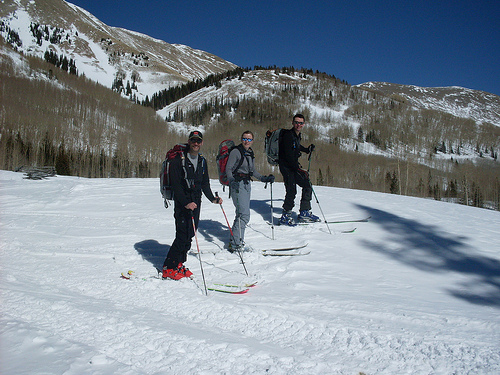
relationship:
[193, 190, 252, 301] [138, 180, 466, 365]
pole used skiing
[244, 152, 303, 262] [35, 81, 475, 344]
pole used skiing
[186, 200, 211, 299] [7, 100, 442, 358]
pole used skiing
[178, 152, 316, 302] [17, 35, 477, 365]
pole used skiing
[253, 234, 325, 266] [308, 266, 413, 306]
ski covered snow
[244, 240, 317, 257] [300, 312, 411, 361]
ski covered snow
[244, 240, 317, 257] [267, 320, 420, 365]
ski covered snow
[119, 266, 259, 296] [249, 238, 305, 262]
ski covered snow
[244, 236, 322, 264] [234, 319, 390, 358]
ski covered snow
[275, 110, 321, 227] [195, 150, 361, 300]
man on skies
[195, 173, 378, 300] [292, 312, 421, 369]
skies in snow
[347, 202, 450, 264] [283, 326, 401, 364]
shadow on snow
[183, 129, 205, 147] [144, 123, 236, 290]
hat on man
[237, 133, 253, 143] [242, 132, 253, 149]
glasses on face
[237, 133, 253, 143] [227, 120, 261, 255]
glasses on man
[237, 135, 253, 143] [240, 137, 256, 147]
glasses of glasses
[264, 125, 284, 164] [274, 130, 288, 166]
pack of back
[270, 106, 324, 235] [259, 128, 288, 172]
man wearing backpack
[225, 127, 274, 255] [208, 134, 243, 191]
man wearing backpack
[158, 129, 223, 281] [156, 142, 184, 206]
man wearing backpack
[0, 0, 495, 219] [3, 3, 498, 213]
range in back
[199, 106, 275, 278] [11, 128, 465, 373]
man on mountain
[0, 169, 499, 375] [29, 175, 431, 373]
snow on hillside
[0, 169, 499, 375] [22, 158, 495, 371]
snow on hillside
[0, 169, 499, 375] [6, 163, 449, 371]
snow on hillside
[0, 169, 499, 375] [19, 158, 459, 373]
snow on hill side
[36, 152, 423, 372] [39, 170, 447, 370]
snow on hill side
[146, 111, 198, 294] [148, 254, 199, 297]
man wearing snow boots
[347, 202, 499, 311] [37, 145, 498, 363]
shadow on snow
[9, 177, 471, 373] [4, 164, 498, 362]
tracks in snow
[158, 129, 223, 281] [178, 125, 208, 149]
man wearing a cap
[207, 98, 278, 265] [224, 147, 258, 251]
woman wearing an outfit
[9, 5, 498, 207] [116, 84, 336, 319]
mountains behind shiers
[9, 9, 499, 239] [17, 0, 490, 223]
trees on mountains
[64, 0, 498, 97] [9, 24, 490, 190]
skies above mountains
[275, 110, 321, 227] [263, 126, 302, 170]
man has a pack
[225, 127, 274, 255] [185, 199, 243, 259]
man has a shadow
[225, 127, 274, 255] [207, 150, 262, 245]
man wearing an outfit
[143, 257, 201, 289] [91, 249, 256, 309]
skiboots attached to skis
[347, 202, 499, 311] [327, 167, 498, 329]
shadow belongs to tree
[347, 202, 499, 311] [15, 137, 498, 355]
shadow on snow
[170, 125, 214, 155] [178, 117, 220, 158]
decal on hat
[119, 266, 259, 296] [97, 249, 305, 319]
ski on skis